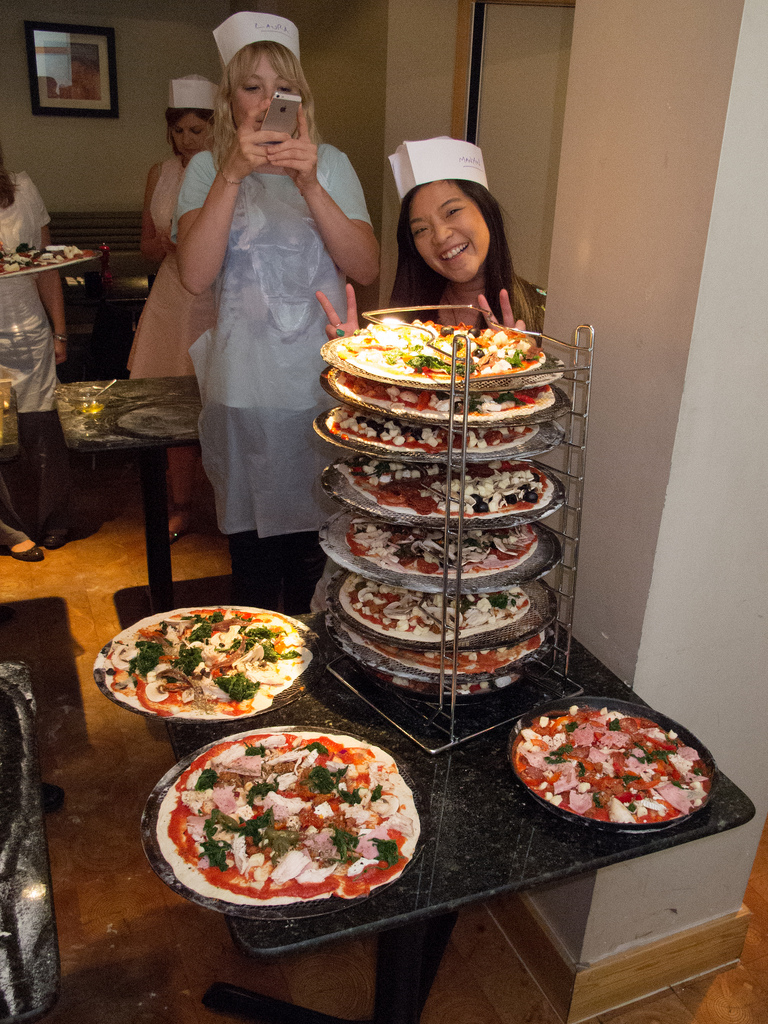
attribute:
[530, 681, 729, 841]
pizza — uncooked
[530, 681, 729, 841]
tray — metal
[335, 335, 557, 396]
pizza — uncooked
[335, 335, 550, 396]
tray — metal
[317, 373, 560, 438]
pizza — uncooked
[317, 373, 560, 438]
tray — metal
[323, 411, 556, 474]
pizza — uncooked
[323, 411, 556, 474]
tray — metal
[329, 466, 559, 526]
pizza — uncooked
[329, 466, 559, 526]
tray — metal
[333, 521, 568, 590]
pizza — uncooked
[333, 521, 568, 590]
tray — metal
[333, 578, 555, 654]
pizza — uncooked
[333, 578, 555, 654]
tray — metal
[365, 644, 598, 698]
pizza — uncooked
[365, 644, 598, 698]
tray — metal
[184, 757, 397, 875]
pizza — round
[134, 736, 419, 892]
pizza — covered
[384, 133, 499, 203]
chef hat — white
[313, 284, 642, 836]
pizzas — uncooked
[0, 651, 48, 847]
bowl — clear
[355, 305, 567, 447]
pizza rack — silver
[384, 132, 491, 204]
paper hat — white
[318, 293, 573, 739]
stack — on top of each other